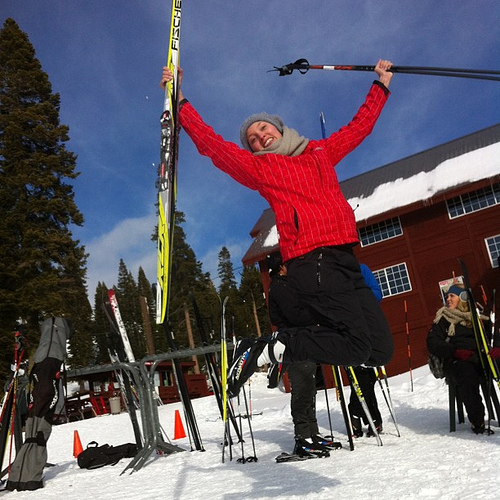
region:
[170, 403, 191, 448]
Orange cone in the snow.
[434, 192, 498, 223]
Window with white trim on the window.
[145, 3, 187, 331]
Ski stick in woman's hand.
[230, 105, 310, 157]
Grey scarf around woman's neck.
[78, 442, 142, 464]
Black bag on the ground.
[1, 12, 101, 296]
Big trees in the corner.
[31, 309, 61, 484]
Grey and black bag in the corner.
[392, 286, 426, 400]
Orange and black stick in snow.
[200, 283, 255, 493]
Ski poles in the back.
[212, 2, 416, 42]
Blue sky with thin clouds.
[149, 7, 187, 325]
ski in hand of skier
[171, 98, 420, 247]
red coat worn by skier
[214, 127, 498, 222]
roof with snow on it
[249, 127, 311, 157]
gray scarf around neck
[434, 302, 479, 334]
gray scarf around neck of skier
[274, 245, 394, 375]
black snow suit on skier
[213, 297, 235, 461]
green and gray ski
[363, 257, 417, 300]
window with white cross bars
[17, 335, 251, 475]
rack for holding skis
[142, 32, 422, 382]
skier jumping in air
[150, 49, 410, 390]
person is jumping in snow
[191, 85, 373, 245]
person is wearing a red snow jackt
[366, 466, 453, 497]
white powdered snow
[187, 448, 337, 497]
shadow of person jumping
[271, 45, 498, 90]
ski sticks on left hand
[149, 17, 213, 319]
skis on right hand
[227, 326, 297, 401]
snow shoes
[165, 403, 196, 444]
red cone on snow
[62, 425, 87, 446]
red cone on snow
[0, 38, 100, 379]
tall pine tree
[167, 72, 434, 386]
woman jumping in snow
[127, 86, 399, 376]
woman jumping in snow holding skis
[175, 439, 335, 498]
shadow of woman jumping holding skis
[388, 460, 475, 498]
white powdery snow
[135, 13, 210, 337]
woman holding skis in right hand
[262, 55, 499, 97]
woman holding ski sicks with left hand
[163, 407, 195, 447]
red cone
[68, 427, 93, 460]
red cone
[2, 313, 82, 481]
skis lying against rail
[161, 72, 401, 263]
bright red ski jacket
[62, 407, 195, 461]
two orange traffic cones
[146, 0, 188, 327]
a yellow snow board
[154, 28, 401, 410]
a woman jumping in the air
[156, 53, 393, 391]
a woman wearing a bright red jacket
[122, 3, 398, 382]
a woman holding a yellow snowboard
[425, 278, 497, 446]
a blonde woman with a blue headband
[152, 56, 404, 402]
a woman wearing a gray hat and beige scarf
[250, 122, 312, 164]
a beige winter scarf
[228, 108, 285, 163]
a gray winter hat